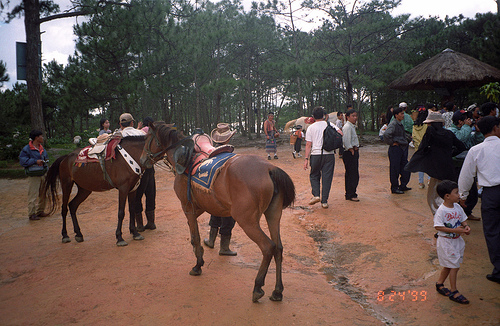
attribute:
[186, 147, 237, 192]
rug — blue, yellow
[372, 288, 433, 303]
date — small, red, rectangular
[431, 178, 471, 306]
child — walking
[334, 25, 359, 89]
tree — tall, green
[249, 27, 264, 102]
tree — tall, green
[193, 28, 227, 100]
tree — tall, green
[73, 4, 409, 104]
trees — tall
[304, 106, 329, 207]
people —  outside,  relaxed, happy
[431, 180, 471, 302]
boy — little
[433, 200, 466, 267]
clothes — white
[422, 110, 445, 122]
hat — tan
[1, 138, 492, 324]
dirt — red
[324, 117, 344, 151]
backpack — black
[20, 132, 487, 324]
ground — red, clay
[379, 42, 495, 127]
hut — straw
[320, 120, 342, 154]
pack — backpack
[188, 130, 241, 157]
saddle — red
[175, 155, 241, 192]
blanket — blue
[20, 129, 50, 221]
man — standing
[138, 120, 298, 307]
brown horse — standing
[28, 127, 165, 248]
brown horse — standing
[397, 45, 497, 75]
roof — thatched, pointed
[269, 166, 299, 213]
tail — wagging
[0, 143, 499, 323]
ground — red, clay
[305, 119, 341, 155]
shirt — white